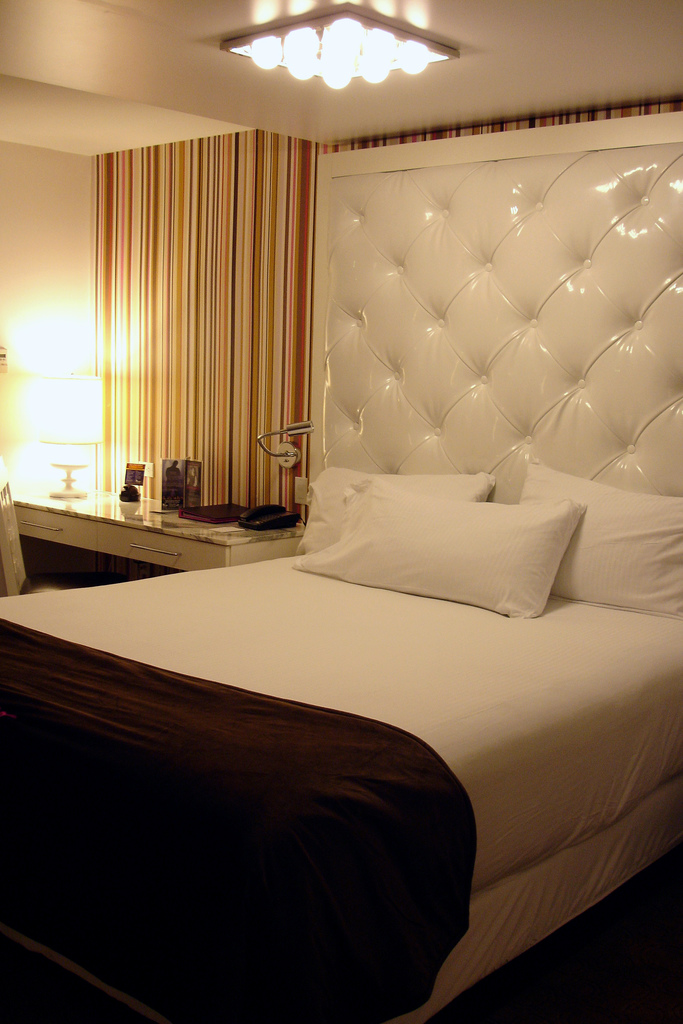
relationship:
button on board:
[462, 356, 493, 392] [315, 152, 658, 505]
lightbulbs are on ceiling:
[221, 17, 438, 105] [4, 6, 652, 126]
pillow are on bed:
[299, 459, 497, 566] [7, 455, 658, 1013]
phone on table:
[199, 481, 302, 545] [15, 453, 339, 580]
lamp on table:
[21, 346, 134, 526] [0, 466, 295, 598]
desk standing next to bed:
[17, 477, 301, 601] [2, 111, 662, 1018]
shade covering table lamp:
[31, 373, 107, 447] [26, 370, 107, 504]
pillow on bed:
[296, 479, 588, 621] [270, 649, 551, 744]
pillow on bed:
[582, 485, 666, 607] [297, 660, 484, 728]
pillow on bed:
[330, 438, 459, 529] [217, 563, 506, 736]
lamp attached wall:
[253, 417, 317, 466] [259, 360, 344, 418]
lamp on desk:
[32, 370, 104, 503] [39, 507, 137, 539]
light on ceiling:
[238, 28, 415, 81] [112, 14, 203, 94]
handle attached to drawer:
[126, 537, 184, 563] [110, 509, 229, 587]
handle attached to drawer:
[25, 507, 58, 544] [13, 510, 65, 542]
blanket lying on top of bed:
[3, 618, 481, 1021] [1, 551, 661, 1021]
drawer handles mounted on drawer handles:
[15, 514, 64, 537] [15, 514, 64, 537]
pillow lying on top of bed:
[289, 474, 588, 621] [1, 551, 661, 1021]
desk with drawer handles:
[17, 478, 301, 602] [6, 504, 195, 568]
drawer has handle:
[9, 495, 303, 564] [126, 539, 181, 565]